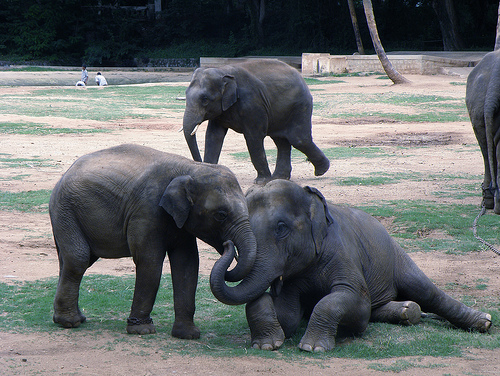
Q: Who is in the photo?
A: No one.